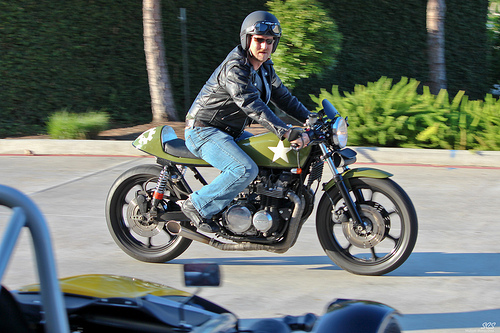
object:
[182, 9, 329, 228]
man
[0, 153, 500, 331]
ground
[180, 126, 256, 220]
jeans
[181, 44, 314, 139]
jacket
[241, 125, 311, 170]
tank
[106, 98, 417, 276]
motorcycle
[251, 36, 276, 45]
goggles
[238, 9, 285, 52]
helmet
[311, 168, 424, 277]
wheel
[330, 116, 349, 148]
headlight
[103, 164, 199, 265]
rear wheel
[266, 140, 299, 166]
white star